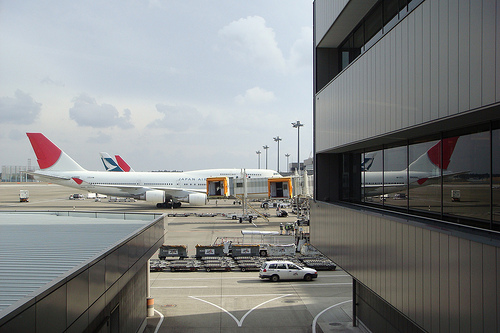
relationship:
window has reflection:
[315, 100, 500, 246] [361, 126, 499, 226]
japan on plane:
[176, 176, 197, 182] [24, 132, 283, 208]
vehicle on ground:
[257, 259, 318, 282] [5, 179, 367, 332]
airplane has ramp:
[24, 132, 283, 208] [204, 176, 293, 200]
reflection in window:
[361, 126, 499, 226] [315, 100, 500, 246]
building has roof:
[0, 211, 165, 331] [0, 210, 167, 320]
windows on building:
[315, 0, 430, 95] [312, 0, 499, 333]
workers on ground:
[275, 220, 297, 237] [5, 179, 367, 332]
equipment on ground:
[17, 187, 31, 202] [5, 179, 367, 332]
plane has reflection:
[24, 132, 283, 208] [361, 126, 499, 226]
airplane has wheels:
[24, 132, 283, 208] [158, 199, 180, 208]